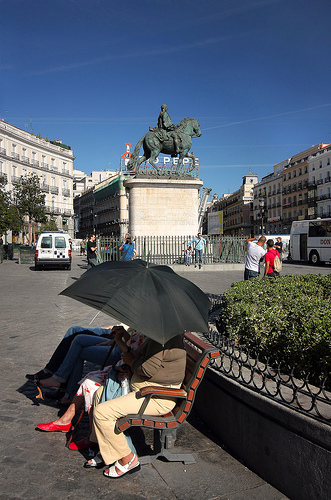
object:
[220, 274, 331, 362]
bush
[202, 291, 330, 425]
fence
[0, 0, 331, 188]
sky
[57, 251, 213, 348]
umbrella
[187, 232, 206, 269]
man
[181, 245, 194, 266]
child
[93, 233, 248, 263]
fence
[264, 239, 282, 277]
man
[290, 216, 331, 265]
bus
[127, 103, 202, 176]
statue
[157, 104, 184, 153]
man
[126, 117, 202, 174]
horse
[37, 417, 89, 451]
red shoes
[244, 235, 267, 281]
man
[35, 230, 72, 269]
van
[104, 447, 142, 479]
sandals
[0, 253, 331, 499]
sidewalk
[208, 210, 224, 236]
sign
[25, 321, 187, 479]
people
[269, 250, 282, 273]
backpack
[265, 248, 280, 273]
shirt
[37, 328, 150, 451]
lady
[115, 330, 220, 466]
bench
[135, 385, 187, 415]
arm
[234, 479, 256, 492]
crack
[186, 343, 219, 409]
wood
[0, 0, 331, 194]
large area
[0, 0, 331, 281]
background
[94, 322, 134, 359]
photo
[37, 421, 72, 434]
feet